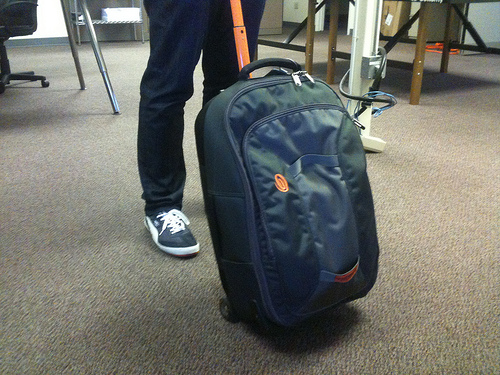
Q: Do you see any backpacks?
A: Yes, there is a backpack.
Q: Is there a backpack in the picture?
A: Yes, there is a backpack.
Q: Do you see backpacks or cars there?
A: Yes, there is a backpack.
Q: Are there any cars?
A: No, there are no cars.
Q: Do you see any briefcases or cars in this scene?
A: No, there are no cars or briefcases.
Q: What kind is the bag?
A: The bag is a backpack.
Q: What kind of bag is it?
A: The bag is a backpack.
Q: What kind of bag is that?
A: This is a backpack.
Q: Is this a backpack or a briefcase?
A: This is a backpack.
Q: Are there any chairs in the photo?
A: Yes, there is a chair.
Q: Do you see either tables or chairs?
A: Yes, there is a chair.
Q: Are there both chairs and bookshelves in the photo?
A: No, there is a chair but no bookshelves.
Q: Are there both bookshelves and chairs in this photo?
A: No, there is a chair but no bookshelves.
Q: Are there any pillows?
A: No, there are no pillows.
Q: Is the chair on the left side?
A: Yes, the chair is on the left of the image.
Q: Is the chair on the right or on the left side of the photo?
A: The chair is on the left of the image.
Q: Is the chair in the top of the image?
A: Yes, the chair is in the top of the image.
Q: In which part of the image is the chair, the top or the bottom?
A: The chair is in the top of the image.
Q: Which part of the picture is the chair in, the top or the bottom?
A: The chair is in the top of the image.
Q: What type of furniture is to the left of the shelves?
A: The piece of furniture is a chair.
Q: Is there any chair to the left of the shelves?
A: Yes, there is a chair to the left of the shelves.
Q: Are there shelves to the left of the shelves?
A: No, there is a chair to the left of the shelves.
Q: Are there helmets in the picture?
A: No, there are no helmets.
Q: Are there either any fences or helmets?
A: No, there are no helmets or fences.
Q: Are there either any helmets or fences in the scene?
A: No, there are no helmets or fences.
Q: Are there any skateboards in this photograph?
A: No, there are no skateboards.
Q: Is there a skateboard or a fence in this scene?
A: No, there are no skateboards or fences.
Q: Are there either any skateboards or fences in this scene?
A: No, there are no skateboards or fences.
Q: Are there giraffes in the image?
A: No, there are no giraffes.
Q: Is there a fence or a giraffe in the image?
A: No, there are no giraffes or fences.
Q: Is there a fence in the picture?
A: No, there are no fences.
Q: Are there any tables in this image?
A: Yes, there is a table.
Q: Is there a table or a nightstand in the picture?
A: Yes, there is a table.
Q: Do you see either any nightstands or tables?
A: Yes, there is a table.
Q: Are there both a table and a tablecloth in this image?
A: No, there is a table but no tablecloths.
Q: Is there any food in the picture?
A: No, there is no food.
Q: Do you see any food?
A: No, there is no food.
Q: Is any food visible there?
A: No, there is no food.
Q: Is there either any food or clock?
A: No, there are no food or clocks.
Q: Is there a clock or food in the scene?
A: No, there are no food or clocks.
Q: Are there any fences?
A: No, there are no fences.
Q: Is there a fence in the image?
A: No, there are no fences.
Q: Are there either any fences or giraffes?
A: No, there are no fences or giraffes.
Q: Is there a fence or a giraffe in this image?
A: No, there are no fences or giraffes.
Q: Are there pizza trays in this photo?
A: No, there are no pizza trays.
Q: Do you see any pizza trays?
A: No, there are no pizza trays.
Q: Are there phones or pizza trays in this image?
A: No, there are no pizza trays or phones.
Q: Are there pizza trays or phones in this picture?
A: No, there are no pizza trays or phones.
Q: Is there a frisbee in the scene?
A: No, there are no frisbees.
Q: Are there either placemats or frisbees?
A: No, there are no frisbees or placemats.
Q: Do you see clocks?
A: No, there are no clocks.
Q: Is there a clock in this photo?
A: No, there are no clocks.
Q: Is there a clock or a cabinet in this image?
A: No, there are no clocks or cabinets.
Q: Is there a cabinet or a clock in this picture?
A: No, there are no clocks or cabinets.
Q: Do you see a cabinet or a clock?
A: No, there are no clocks or cabinets.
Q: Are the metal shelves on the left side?
A: Yes, the shelves are on the left of the image.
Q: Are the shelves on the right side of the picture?
A: No, the shelves are on the left of the image.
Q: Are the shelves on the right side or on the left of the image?
A: The shelves are on the left of the image.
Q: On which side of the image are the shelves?
A: The shelves are on the left of the image.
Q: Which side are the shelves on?
A: The shelves are on the left of the image.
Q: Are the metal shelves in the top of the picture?
A: Yes, the shelves are in the top of the image.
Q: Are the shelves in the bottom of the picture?
A: No, the shelves are in the top of the image.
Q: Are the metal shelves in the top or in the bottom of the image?
A: The shelves are in the top of the image.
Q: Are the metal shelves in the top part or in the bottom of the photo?
A: The shelves are in the top of the image.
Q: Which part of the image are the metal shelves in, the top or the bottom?
A: The shelves are in the top of the image.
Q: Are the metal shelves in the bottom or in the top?
A: The shelves are in the top of the image.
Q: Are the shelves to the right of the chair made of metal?
A: Yes, the shelves are made of metal.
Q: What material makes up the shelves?
A: The shelves are made of metal.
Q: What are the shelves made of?
A: The shelves are made of metal.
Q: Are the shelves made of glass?
A: No, the shelves are made of metal.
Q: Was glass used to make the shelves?
A: No, the shelves are made of metal.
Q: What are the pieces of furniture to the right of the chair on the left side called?
A: The pieces of furniture are shelves.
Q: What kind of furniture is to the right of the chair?
A: The pieces of furniture are shelves.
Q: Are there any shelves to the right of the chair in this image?
A: Yes, there are shelves to the right of the chair.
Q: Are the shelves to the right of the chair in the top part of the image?
A: Yes, the shelves are to the right of the chair.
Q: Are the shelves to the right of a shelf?
A: No, the shelves are to the right of the chair.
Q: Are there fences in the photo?
A: No, there are no fences.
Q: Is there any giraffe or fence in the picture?
A: No, there are no fences or giraffes.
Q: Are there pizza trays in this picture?
A: No, there are no pizza trays.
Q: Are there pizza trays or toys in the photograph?
A: No, there are no pizza trays or toys.